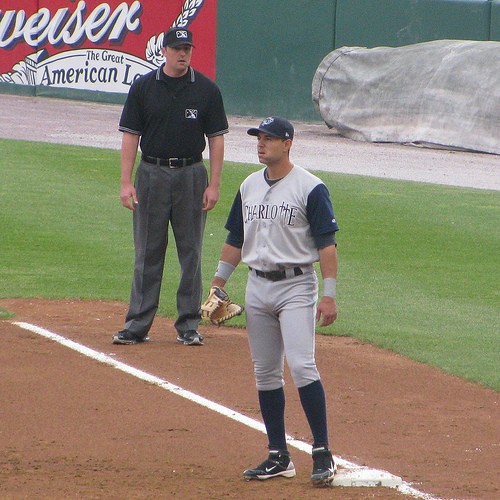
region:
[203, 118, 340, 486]
a baseball player on a baseball field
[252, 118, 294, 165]
a baseball playing chewing something in his mouth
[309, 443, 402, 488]
baseball player with his foot touching a white plate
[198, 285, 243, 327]
a leather catcher's mitt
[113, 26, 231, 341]
an umpire standing on a baseball field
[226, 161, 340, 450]
baseball player wearing a white and blue uniform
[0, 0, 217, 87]
an advertisement on a green wall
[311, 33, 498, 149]
a white tarp on the floor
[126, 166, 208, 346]
man wearing gray pants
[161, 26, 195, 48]
man wearing a black cap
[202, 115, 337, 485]
the baseball player standing at the plate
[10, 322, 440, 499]
the white line on the dirt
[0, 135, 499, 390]
the area of green grass on the field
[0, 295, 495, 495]
the dirt area on the field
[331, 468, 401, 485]
the white base on the field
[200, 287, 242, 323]
the mitt on the catcher's hand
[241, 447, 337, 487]
the shoes on the player's feet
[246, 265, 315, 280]
the belt on the pants of the baseball player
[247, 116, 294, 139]
the hat on the baseball player's head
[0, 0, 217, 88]
the banner hanging on the wall in the back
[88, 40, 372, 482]
two men standing on a baseball field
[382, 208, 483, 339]
green grass of the field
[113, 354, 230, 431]
white stripe on the field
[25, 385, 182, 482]
brown dirt of the baseball field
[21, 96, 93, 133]
tan dirt of the warning track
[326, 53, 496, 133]
canvas sleeve over the field cover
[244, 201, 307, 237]
black lettering on the grey jersey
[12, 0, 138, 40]
white lettering on a red sign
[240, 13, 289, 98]
green wall of the outfield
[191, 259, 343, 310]
grey bands on the player's wrists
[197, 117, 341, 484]
baseball player on the base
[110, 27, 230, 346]
umpire watching the baseball game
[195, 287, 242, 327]
light brown glove on the player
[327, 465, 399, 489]
white base with dirt on it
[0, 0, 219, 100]
red and white advertisement on the wall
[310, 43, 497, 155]
rolled up tarp next to the field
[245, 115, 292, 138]
dark blue and white hat on the baseball player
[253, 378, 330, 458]
dark blue knee high socks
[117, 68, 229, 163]
black shirt on the umpire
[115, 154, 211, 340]
gray khakis on the umpire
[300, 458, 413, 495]
a base on the baseball field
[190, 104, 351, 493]
a man wearing a baseball uniform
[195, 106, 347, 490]
a man wearing a baseball glove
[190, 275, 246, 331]
the baseball glove on the man's hand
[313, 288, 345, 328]
the baseball player's left hand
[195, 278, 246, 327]
the baseball player's right hand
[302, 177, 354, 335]
the baseball player's left arm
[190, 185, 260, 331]
the baseball player's right arm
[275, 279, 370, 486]
the baseball player's left leg